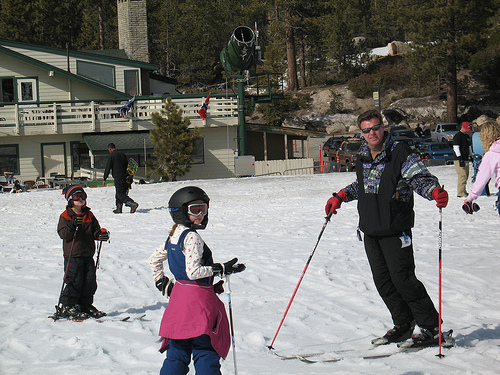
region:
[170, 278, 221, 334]
girl with pink jacket around waist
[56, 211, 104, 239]
child wearing black and red jacket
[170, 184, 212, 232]
girl wearing black helmet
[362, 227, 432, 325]
man wearing black pants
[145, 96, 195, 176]
tree with green branches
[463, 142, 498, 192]
woman wearing pink sweater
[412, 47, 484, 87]
trees with green branches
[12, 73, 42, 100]
blue and white door on house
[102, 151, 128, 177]
man wearing black shirt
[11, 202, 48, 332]
white snow with tracks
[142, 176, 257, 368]
girl wearing black helmet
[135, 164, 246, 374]
girl has pink jacket around her waist.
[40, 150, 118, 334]
boy wearing black and red hat.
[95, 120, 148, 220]
man carrying a snowboard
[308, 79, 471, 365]
man wearing dark sunglasses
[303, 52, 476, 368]
man wearing red gloves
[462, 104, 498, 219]
woman wearing pink sweatshirt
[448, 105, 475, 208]
man wearing red baseball cap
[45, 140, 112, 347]
boy wearing brown and red jacket.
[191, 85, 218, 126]
flag on the front of the building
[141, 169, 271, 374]
girl with a pink jacket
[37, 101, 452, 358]
a family preparing to ski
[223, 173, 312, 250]
ground covered by snow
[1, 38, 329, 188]
a ski lodge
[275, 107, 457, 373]
A man on skis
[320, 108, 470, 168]
a parking lot filled with cars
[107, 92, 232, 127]
flags hanging on a building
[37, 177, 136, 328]
a young boy on skis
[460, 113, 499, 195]
a blonde woman in pink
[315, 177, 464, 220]
red gloves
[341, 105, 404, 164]
A man wearing glasses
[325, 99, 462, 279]
A man with red ski gloves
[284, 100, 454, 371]
A man with ski poles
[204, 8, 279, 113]
A snow making machine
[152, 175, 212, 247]
A girl wearing a helmet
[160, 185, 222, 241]
A girl wearing goggles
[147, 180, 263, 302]
A girl with black ski gloves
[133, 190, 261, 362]
A girl with a pink jacket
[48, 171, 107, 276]
A boy with goggles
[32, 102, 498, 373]
people skiing at a resort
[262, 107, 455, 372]
man skiing with poles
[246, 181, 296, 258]
white snow on the ground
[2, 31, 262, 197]
building in the background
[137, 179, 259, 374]
young girl in the snow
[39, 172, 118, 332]
young boy skiing with poles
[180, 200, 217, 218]
eye goggles on a young girl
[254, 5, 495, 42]
green trees in the background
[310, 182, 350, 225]
red glove on man's right hand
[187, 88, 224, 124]
flag hanging on side of a building